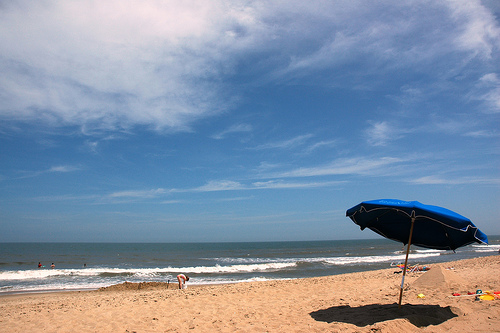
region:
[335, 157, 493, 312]
the blue umbrella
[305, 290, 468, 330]
the shade of the umbrella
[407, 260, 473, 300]
the sand pyramid next to the umbrella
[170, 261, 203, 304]
the child bending over in the sand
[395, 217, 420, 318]
the pole of the umbrella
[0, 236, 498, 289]
the calm ocean water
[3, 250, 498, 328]
the brown and tan sand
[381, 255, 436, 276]
the person on a lounge chair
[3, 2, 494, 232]
the sky has clouds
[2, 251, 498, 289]
the waves are cresting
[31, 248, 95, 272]
people in the water at the beach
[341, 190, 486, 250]
a blue umbrella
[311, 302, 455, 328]
a shadow of the umbrella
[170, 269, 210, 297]
a person standing on the beach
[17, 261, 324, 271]
waves in the ocean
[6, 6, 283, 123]
a cloud in the sky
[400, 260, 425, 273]
a chair on the beach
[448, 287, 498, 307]
toys on the beach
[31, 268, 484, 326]
sand on the beach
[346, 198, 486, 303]
a blue umbrella on the beach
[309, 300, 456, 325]
shadow on the sand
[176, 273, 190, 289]
a person is bending over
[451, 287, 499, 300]
sand toys spread out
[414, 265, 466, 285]
a pyramid shaped sand structure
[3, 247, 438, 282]
white tops on the waves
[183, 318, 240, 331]
footprints on the sand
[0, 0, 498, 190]
clouds in the sky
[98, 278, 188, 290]
a pile of sand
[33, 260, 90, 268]
three people swimming in the water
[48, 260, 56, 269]
A swimming in distance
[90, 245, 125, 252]
Part of the water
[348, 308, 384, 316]
Part of the shadow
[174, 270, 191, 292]
A person playing in the sand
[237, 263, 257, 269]
Part of the wave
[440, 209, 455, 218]
Part of the blue umbrella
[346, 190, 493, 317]
A blue beach umbrella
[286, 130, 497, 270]
an umbrella on the beach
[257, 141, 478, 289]
an umbrella in the sand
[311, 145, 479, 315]
a blue umbrella on teh sand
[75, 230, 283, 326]
a body of water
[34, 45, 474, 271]
a sky taht is blue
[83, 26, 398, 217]
a sky with clouds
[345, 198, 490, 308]
large blue umbrella on the beach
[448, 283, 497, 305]
pile of toys in the sand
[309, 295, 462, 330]
shade created by umbrella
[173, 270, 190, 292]
girl bent over at the shore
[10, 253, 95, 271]
people past the first wave in the water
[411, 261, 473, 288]
pyramid created with sand on beach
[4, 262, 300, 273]
white water created by waves crashing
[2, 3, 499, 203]
swirls of clouds in a blue sky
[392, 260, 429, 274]
lounge chair in sand on beach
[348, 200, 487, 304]
a large blue umbrella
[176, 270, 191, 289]
a person bending over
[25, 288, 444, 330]
sand on the beach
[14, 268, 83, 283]
waves in the water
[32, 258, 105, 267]
people in the water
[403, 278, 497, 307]
toys in the sand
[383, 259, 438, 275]
a person laying in they sand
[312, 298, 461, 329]
the shadow from the umbrella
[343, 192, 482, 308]
a large open umbrella